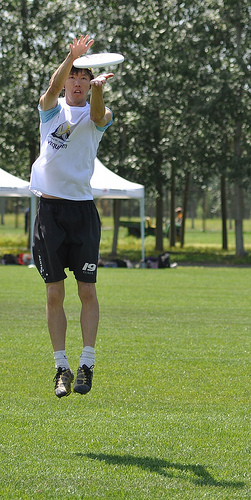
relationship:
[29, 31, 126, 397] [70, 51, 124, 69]
man catching frisbee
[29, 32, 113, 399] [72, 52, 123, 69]
man catching frisbee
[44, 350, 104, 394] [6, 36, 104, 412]
feet on man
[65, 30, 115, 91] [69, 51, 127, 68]
hands catching frisbee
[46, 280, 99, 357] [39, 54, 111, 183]
legs on man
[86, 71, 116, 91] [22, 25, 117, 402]
hand on man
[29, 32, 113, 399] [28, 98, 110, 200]
man wearing shirt